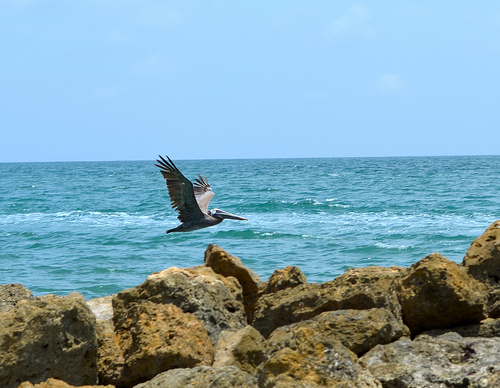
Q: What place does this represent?
A: It represents the shore.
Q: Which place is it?
A: It is a shore.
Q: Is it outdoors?
A: Yes, it is outdoors.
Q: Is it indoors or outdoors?
A: It is outdoors.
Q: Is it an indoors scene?
A: No, it is outdoors.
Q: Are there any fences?
A: No, there are no fences.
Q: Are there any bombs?
A: No, there are no bombs.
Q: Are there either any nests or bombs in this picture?
A: No, there are no bombs or nests.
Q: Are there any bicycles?
A: No, there are no bicycles.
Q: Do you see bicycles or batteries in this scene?
A: No, there are no bicycles or batteries.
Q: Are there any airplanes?
A: No, there are no airplanes.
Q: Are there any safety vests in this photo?
A: No, there are no safety vests.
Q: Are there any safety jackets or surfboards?
A: No, there are no safety jackets or surfboards.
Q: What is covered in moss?
A: The rock is covered in moss.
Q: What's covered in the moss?
A: The rock is covered in moss.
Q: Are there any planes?
A: No, there are no planes.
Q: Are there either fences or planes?
A: No, there are no planes or fences.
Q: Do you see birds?
A: Yes, there is a bird.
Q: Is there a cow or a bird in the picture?
A: Yes, there is a bird.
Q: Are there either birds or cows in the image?
A: Yes, there is a bird.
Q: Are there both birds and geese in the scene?
A: No, there is a bird but no geese.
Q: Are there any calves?
A: No, there are no calves.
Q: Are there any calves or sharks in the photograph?
A: No, there are no calves or sharks.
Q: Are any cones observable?
A: No, there are no cones.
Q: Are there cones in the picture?
A: No, there are no cones.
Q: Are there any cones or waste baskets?
A: No, there are no cones or waste baskets.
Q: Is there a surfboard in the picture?
A: No, there are no surfboards.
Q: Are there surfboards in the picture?
A: No, there are no surfboards.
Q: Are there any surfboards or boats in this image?
A: No, there are no surfboards or boats.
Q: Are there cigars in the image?
A: No, there are no cigars.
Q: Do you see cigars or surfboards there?
A: No, there are no cigars or surfboards.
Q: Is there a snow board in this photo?
A: No, there are no snowboards.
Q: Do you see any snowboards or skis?
A: No, there are no snowboards or skis.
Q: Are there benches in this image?
A: No, there are no benches.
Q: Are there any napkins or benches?
A: No, there are no benches or napkins.